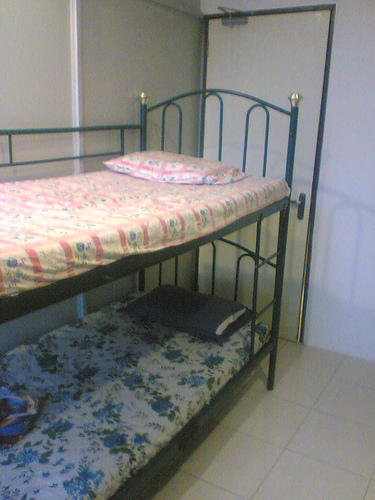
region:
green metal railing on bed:
[245, 221, 261, 354]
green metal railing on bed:
[255, 298, 276, 318]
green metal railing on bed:
[257, 251, 277, 271]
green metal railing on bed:
[231, 254, 258, 313]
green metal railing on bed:
[190, 241, 218, 291]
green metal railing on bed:
[154, 256, 179, 289]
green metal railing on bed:
[136, 268, 147, 290]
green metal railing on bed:
[220, 238, 274, 268]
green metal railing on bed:
[240, 103, 268, 175]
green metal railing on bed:
[197, 90, 223, 161]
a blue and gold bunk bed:
[0, 86, 303, 498]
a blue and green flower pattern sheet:
[0, 282, 280, 497]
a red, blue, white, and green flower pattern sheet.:
[2, 168, 295, 303]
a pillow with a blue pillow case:
[118, 279, 262, 350]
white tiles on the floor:
[139, 337, 373, 497]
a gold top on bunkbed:
[283, 86, 306, 107]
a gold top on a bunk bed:
[135, 85, 152, 103]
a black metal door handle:
[282, 181, 312, 225]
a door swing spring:
[214, 3, 253, 29]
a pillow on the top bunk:
[100, 138, 252, 186]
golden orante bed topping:
[114, 69, 158, 114]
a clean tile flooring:
[235, 400, 343, 492]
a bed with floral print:
[35, 340, 204, 442]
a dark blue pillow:
[132, 258, 243, 351]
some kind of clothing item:
[3, 375, 48, 450]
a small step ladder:
[242, 200, 295, 375]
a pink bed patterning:
[35, 173, 242, 248]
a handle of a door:
[275, 162, 311, 228]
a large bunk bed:
[74, 90, 314, 377]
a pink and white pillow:
[114, 135, 243, 204]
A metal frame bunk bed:
[4, 76, 309, 484]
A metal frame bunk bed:
[6, 80, 307, 485]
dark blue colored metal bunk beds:
[0, 84, 307, 498]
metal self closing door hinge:
[212, 2, 252, 31]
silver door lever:
[282, 190, 308, 222]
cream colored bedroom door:
[187, 1, 343, 346]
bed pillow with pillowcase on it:
[99, 145, 251, 188]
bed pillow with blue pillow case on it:
[112, 281, 259, 348]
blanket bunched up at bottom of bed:
[1, 373, 42, 448]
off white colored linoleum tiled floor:
[100, 332, 373, 498]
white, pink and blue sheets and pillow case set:
[1, 147, 294, 299]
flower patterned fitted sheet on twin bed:
[0, 287, 276, 499]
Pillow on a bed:
[103, 139, 248, 193]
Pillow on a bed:
[127, 280, 257, 348]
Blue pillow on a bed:
[130, 279, 260, 355]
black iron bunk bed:
[2, 76, 304, 491]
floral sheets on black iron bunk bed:
[4, 141, 291, 298]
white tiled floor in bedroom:
[148, 337, 369, 494]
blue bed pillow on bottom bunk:
[124, 284, 253, 349]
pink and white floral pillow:
[103, 142, 243, 191]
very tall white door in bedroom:
[180, 2, 354, 345]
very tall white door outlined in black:
[199, 0, 338, 340]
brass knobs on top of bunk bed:
[133, 85, 301, 113]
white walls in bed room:
[2, 1, 250, 345]